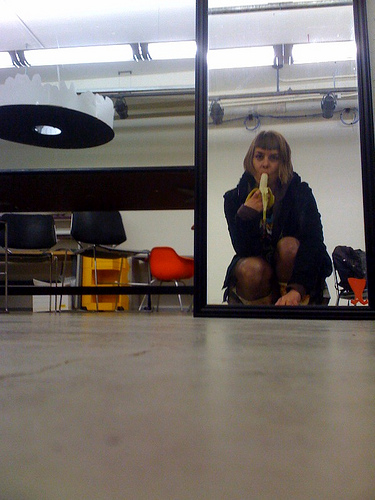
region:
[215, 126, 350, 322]
The woman is in the mirror eating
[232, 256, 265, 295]
The knee of the woman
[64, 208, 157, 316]
The chair on the floor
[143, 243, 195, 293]
The chair is the color orange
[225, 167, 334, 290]
The woman is wearing a black jacket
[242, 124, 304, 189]
The woman has blonde brown hair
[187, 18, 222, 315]
The rim of the mirror is black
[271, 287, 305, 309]
The hand of the woman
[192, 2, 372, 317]
mirror with black frame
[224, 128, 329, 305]
image of woman in mirror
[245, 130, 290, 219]
banana in woman's mouth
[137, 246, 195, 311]
back of red chair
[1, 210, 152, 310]
black chairs with metal legs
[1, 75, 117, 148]
round structure hanging from ceiling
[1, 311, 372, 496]
smooth gray floor surface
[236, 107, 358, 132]
blue wires on wall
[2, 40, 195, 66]
long lights on ceiling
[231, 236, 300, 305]
two knees of woman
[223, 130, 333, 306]
a woman squating down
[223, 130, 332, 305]
a woman eating a banana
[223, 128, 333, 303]
a woman dressed in black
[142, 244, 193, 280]
a small orange palstic chair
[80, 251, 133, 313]
a hard yellow palstic object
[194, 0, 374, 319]
a black framed mirror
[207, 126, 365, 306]
a mirror reflection of a woman squating down eating a banana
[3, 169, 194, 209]
a folding table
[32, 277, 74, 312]
a white cardboard box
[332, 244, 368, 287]
reflection of a backpack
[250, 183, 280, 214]
Person holding banana in hand.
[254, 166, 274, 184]
Person eating yellow banana.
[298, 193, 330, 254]
Person wearing black coat.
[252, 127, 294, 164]
Person has brown hair.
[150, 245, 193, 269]
Orange chair near wall.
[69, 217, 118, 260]
Black chair in room.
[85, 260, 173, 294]
Black chair has silver legs.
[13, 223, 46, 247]
Black chair in room.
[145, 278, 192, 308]
Silver legs on red chair.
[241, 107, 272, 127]
Blue cord near wall.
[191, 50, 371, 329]
Woman's reflection in a mirror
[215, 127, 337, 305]
Woman eating a banana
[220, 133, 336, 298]
Woman wearing a black coat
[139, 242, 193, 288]
The chair is red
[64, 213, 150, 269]
The chari is black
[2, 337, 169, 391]
The floor has a crack in it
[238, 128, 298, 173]
Woman's hair is blonde with short bangs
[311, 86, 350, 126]
Black spot light with blue wires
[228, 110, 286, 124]
Blue wires attached to the wall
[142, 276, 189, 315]
Silver legs on the chair